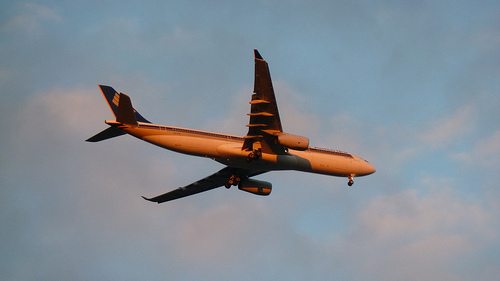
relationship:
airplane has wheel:
[84, 49, 377, 205] [348, 180, 355, 187]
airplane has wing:
[84, 49, 377, 205] [119, 92, 138, 124]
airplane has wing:
[84, 49, 377, 205] [84, 126, 127, 143]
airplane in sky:
[84, 49, 377, 205] [0, 0, 500, 281]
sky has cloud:
[0, 0, 500, 281] [39, 91, 179, 185]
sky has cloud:
[0, 0, 500, 281] [371, 196, 470, 267]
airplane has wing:
[84, 49, 377, 205] [248, 47, 283, 144]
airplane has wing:
[84, 49, 377, 205] [141, 166, 246, 204]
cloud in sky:
[39, 91, 179, 185] [0, 0, 500, 281]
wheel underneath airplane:
[348, 180, 355, 187] [84, 49, 377, 205]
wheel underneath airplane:
[246, 152, 258, 162] [84, 49, 377, 205]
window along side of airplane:
[173, 127, 176, 130] [84, 49, 377, 205]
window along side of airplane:
[185, 129, 188, 133] [84, 49, 377, 205]